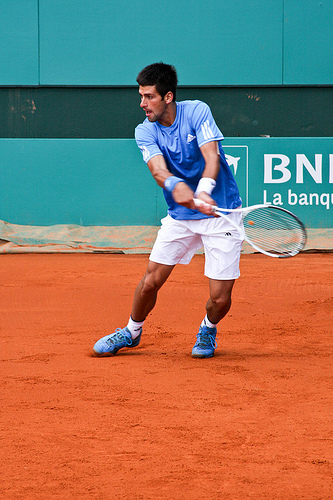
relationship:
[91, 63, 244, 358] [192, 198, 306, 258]
man swinging h racket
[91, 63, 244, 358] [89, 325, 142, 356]
man wearing shoe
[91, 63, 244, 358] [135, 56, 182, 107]
man has hair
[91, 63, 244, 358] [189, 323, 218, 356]
man wearing shoe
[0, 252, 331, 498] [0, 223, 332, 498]
dirt on ground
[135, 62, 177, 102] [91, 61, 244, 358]
hair on man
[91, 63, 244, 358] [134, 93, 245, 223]
man wearing shirt